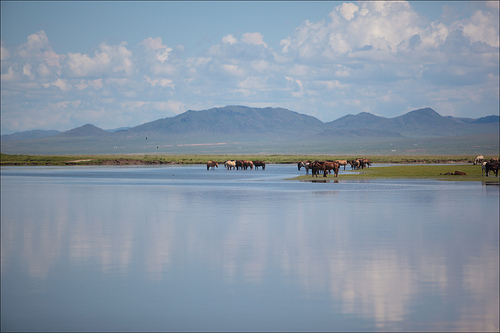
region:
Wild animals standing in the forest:
[203, 150, 499, 187]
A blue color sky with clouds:
[62, 16, 366, 64]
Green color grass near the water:
[383, 162, 435, 176]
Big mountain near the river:
[81, 96, 438, 146]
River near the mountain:
[68, 188, 321, 279]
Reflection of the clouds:
[36, 195, 426, 298]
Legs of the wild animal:
[323, 170, 340, 181]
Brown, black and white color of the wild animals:
[193, 152, 498, 184]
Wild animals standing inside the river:
[201, 155, 271, 176]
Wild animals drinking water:
[246, 156, 271, 173]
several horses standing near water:
[280, 147, 407, 197]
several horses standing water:
[206, 148, 276, 186]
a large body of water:
[0, 163, 445, 270]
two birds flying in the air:
[133, 121, 170, 158]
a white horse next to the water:
[472, 151, 484, 167]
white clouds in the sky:
[160, 18, 430, 96]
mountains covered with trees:
[5, 101, 478, 155]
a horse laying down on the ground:
[420, 159, 467, 191]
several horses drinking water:
[203, 148, 273, 184]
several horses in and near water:
[160, 139, 429, 216]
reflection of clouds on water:
[1, 189, 497, 324]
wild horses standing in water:
[205, 153, 372, 180]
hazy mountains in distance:
[1, 103, 498, 150]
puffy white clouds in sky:
[13, 11, 493, 105]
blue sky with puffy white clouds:
[2, 0, 499, 120]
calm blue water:
[5, 160, 498, 330]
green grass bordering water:
[307, 163, 497, 182]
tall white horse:
[222, 160, 236, 170]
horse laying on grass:
[436, 168, 466, 178]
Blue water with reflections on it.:
[1, 162, 498, 331]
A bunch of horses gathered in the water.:
[203, 158, 266, 170]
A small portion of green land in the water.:
[294, 162, 499, 185]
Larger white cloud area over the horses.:
[269, 1, 498, 116]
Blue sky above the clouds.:
[1, 0, 306, 33]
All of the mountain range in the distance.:
[1, 105, 498, 155]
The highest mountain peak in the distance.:
[408, 107, 443, 122]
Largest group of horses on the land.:
[296, 154, 372, 175]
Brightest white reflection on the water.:
[326, 244, 418, 323]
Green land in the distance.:
[1, 150, 493, 164]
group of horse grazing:
[186, 145, 371, 176]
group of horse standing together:
[189, 153, 368, 184]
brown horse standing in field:
[318, 159, 340, 173]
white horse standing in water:
[226, 153, 234, 170]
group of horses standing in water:
[197, 151, 272, 173]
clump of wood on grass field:
[431, 163, 469, 177]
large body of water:
[32, 185, 227, 330]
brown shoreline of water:
[97, 157, 154, 170]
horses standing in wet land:
[181, 148, 368, 193]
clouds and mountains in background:
[140, 53, 297, 148]